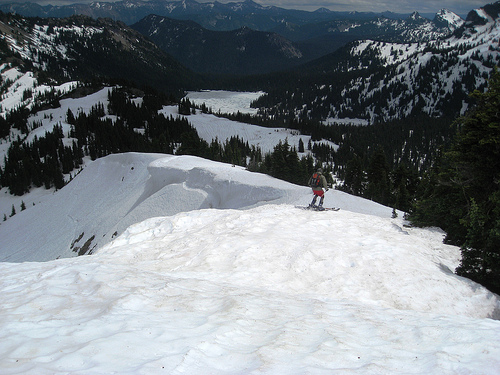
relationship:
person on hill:
[307, 168, 328, 211] [5, 209, 490, 374]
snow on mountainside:
[23, 21, 133, 94] [9, 12, 159, 109]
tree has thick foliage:
[366, 145, 393, 207] [376, 149, 432, 208]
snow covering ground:
[0, 90, 497, 372] [2, 152, 497, 373]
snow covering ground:
[0, 90, 497, 372] [123, 205, 461, 354]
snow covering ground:
[0, 90, 497, 372] [238, 281, 485, 372]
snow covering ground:
[0, 90, 497, 372] [158, 242, 465, 368]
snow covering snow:
[0, 90, 497, 372] [0, 90, 497, 372]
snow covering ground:
[0, 90, 497, 372] [174, 216, 368, 326]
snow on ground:
[0, 90, 497, 372] [2, 152, 497, 373]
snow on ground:
[0, 90, 497, 372] [194, 201, 488, 372]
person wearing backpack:
[307, 168, 328, 211] [310, 173, 322, 188]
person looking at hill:
[307, 168, 328, 211] [5, 209, 490, 374]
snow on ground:
[0, 90, 497, 372] [9, 227, 481, 373]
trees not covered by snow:
[402, 61, 499, 228] [0, 0, 499, 372]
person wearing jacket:
[301, 167, 341, 215] [309, 171, 325, 192]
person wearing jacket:
[307, 168, 328, 211] [312, 171, 331, 197]